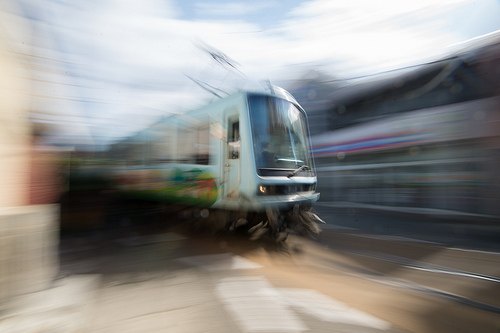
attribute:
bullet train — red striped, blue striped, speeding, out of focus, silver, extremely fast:
[314, 43, 499, 223]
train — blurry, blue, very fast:
[246, 94, 316, 178]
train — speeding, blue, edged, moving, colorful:
[78, 84, 320, 239]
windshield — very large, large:
[246, 92, 318, 179]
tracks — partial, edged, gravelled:
[274, 222, 499, 311]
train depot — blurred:
[2, 3, 86, 295]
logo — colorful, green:
[88, 169, 222, 208]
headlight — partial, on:
[259, 183, 270, 196]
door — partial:
[224, 112, 246, 198]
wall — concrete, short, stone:
[2, 207, 60, 298]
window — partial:
[179, 120, 216, 166]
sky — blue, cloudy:
[4, 1, 499, 150]